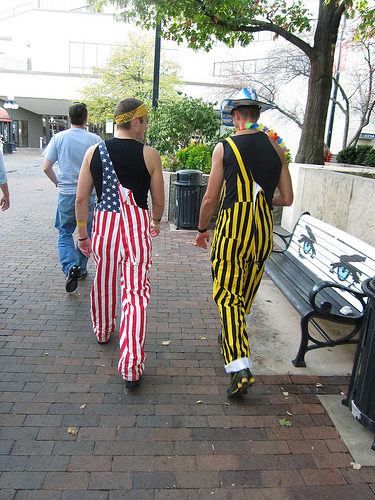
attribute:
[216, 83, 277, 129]
hat — white, blue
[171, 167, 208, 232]
trashcan — black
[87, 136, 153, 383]
overalls — blue, red, white, american flag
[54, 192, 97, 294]
jeans — blue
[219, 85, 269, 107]
hat — blue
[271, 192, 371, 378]
bench — black, white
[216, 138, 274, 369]
overalls — yellow, black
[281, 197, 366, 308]
bench — black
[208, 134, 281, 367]
clothes — black, yellow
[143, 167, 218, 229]
trashcan — black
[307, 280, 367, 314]
armrest — metal, curved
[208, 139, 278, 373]
overalls — striped, black, yellow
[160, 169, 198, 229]
garbage can — round, black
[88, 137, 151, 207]
tank top — black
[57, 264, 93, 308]
shoe — black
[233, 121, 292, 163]
lei — multi-colored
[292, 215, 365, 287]
eyes — painted